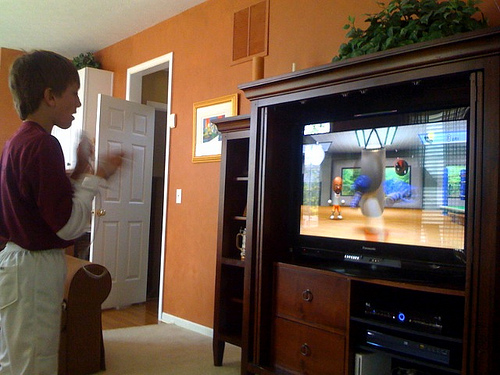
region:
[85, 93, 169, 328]
White door in a house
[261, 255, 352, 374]
Brown drawers on a shelf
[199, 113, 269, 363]
Brown book shelf by a wall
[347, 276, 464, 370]
DVD player on a stand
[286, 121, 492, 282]
TV on a stand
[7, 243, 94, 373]
White pants on a boy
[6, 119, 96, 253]
Maroon shirt on a boy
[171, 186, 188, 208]
White light switch on a wall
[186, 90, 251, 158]
Picture on a wall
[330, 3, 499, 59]
Plant on a stand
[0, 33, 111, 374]
little boy with short brown hair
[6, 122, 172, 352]
little boy with short sleeve burgundy shirt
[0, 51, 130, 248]
little boy with white long sleeve undershirt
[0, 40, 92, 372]
little boy with white long pants on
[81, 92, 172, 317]
white door with brass door knob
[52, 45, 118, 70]
small green plant on top of cabinet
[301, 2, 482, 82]
large green plant on top of tv unit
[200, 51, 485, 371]
television entertainment center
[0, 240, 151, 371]
large arm on a sofa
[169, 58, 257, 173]
large matted and framed picture hanging on the wall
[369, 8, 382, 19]
a green tree leaf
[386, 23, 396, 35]
a green tree leaf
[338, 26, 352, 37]
a green tree leaf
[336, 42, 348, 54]
a green tree leaf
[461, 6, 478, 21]
a green tree leaf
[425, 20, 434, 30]
a green tree leaf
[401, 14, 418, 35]
a green tree leaf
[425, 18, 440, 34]
a green tree leaf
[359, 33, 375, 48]
a green tree leaf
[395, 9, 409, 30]
a green tree leaf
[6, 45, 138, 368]
boy standing in living room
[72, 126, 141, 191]
moving hands with game control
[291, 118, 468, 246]
video game on television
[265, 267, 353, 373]
draws on entertainment unit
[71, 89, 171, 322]
open white door with gold knob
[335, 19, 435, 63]
leaves of plant on unit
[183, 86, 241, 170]
picture in gold frame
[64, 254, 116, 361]
arm of brown couch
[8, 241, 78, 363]
white pants on boy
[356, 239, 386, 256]
name of television brand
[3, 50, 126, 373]
a boy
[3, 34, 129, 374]
a boy holding remote controls in his hands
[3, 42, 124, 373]
the boy is standing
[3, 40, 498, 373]
the boy is playing a game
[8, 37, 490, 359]
the boy stands in front of a television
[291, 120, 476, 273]
a television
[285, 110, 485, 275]
a video game on the television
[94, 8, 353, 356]
the walls are orange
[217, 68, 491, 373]
the television is in a wood cabinet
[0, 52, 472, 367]
the boy is playing a boxing game